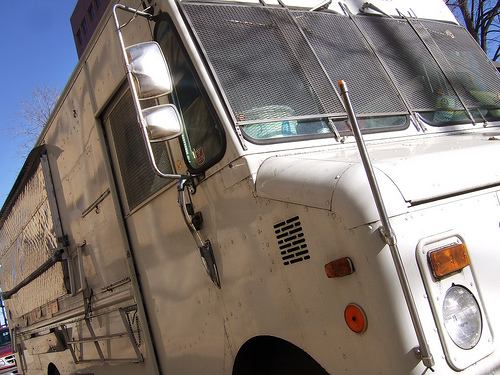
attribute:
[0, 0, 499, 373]
van — white, large, sunny, out of service, a food truck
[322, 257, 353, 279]
signal — amber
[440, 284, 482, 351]
headlight — white, pushed in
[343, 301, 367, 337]
reflector — round, orange, amber, circular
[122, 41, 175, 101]
rear view mirror — metal, rectangular, long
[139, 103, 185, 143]
rear view mirror — metal, rectangular, short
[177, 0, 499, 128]
windshield protector — chain mesh, metal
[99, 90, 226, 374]
door — white, sliding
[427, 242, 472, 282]
light — orange, rectangular, poked out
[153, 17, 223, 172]
window — on the side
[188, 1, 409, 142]
windshield — clear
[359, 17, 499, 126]
windshield — clear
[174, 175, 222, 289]
handel — metal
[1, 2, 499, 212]
sky — cloudless, blue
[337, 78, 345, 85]
tip — orange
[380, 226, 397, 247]
brackets — silvertone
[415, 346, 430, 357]
brackets — silvertone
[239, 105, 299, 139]
bucket — pale